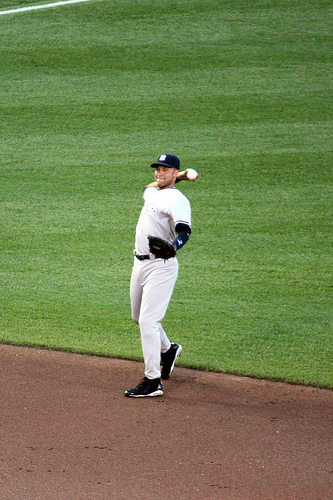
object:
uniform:
[130, 187, 191, 381]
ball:
[186, 168, 197, 179]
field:
[0, 0, 333, 391]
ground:
[0, 337, 332, 500]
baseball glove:
[147, 235, 177, 260]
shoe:
[124, 377, 163, 399]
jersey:
[135, 187, 192, 257]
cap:
[150, 153, 180, 170]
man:
[124, 153, 198, 399]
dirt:
[0, 343, 332, 499]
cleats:
[124, 343, 182, 398]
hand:
[147, 235, 176, 259]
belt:
[135, 254, 161, 260]